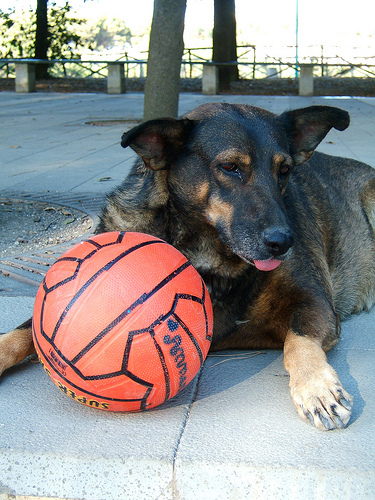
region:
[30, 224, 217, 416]
a ball on ground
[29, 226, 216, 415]
orange ball with black lines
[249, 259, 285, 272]
a tongue is pink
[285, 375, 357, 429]
the paw of dog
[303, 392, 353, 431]
the nails of paw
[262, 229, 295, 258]
dog black nose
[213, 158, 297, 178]
eyes are open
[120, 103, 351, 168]
wagging of dog ears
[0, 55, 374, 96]
green benches for sitting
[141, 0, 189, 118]
a tree behind dog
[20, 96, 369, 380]
dog is laying on the ground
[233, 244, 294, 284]
the tongue is out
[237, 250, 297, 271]
the tongue is pink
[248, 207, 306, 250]
the nose is black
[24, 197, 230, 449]
a basket ball near the dog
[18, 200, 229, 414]
the ball is orange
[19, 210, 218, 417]
the ball has black lines on it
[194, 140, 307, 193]
the eyes are open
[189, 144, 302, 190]
the eyes are brown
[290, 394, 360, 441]
the nails are grey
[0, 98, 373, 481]
brindle dog laying on sidewalk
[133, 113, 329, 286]
dog's eyes need cleaned out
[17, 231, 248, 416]
basketball with blue writing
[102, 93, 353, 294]
dog with tongue sticking out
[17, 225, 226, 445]
ball with black writing on it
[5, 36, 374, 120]
concrete benches in background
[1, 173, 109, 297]
drain cover with dirt on it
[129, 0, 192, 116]
tree trunk in middle of space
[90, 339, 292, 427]
sun casating shadows on sidewalk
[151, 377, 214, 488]
crack in sidewalk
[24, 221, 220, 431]
the ball is orange and black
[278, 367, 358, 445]
the dog has a front paw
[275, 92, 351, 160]
the dog has an ear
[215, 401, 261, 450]
the concrete is white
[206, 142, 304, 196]
the dog has eyes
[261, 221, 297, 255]
the dog has a nose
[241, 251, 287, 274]
the dog has a tongue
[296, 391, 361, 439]
the dog has nails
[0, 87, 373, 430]
the dog is lying down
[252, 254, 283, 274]
the tongue is pink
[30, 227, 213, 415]
A red football with black lines on it.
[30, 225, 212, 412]
A red football on the ground.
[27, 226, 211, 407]
A football on concrete ground.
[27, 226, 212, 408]
A football in front of a dog.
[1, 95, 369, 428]
A dark brownish dog lying on ground.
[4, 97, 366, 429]
A dog lying next to a football.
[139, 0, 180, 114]
A tree trunk behind the dog.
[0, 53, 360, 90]
Short stone pillars in the background.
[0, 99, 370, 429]
A brownish dog with its tongue out.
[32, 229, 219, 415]
A football with black lines and letters on it.